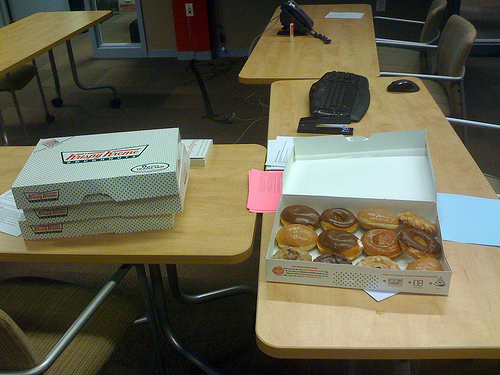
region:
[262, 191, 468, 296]
BOX OF ASSORTED DONUTS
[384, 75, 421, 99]
BLACK COMPUTER MOUSE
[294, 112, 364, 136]
BLACK STAPLER ON TABLE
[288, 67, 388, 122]
COMPUTER KEYBOARD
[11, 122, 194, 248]
THREE DOUGHNUT BOXES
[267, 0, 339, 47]
A CORDED TELEPHONE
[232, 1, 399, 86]
WOODEN TABLE TOP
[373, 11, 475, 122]
BROWN CHAIR NEXT TO THE TABLE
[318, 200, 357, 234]
A CHOCOLATE COVERED DOUGHNUT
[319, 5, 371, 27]
SHEET OF PAPER ON TOP OF THE TABLE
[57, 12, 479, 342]
boxes of doughnuts in a room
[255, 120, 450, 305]
a dozen doughnuts in an open box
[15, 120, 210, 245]
three cardboard boxes in a stack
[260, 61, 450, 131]
keyboard, mouse and stapler on a desk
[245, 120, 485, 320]
blue, pink and white papers around a box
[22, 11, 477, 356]
light and rectangular tables next to each other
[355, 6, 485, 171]
chairs with thin metal arms facing table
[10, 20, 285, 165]
open space in the center of tables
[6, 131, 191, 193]
rectangular lidded box in green, red and white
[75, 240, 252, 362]
metal table supports curved in different directions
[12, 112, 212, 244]
three boxes of krispy kreme donuts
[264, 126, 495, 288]
open box of donuts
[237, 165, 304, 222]
pink papers on table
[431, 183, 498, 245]
blue papers on table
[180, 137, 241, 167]
book on table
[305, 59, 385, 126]
black keyboard on the table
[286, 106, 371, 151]
black stapler on the table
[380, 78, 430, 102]
black mouse on the table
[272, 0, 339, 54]
black phone on the table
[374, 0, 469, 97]
two chairs behind desk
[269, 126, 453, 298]
AN OPEN BOX OF DONUTS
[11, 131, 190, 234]
THREE BOXES OF DONUTS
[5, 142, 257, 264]
A TABLE HOLDING THE CLOSED BOXES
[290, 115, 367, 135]
A BLACK STAPLER ON THE TABLE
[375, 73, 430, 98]
A WIRELESS COMPUTER MOUSE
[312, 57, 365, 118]
A WIRELESS COMPUTER KEYBOARD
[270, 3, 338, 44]
A TELEPHONE ON THE TABLE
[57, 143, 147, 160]
A KRISPY KREME LOGO ON THE BOX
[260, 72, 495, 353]
A TABLE ON THE FRONT RIGHT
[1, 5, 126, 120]
A TABLE AT THE REAR LEFT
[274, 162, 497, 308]
Doughnuts are on the table.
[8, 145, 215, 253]
Three boxes of doughnut sits on the table.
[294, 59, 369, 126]
The keyboard is black.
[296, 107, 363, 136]
A stapler is next to the keyboard.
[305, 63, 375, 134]
The keyboard is on the table.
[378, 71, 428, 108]
A mouse is laying on the table beside the keyboard.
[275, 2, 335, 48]
The telephone is on the table.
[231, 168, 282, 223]
The paper is pink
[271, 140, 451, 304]
The box of doughnut is open.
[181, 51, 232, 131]
Black tape is on the floor in a line